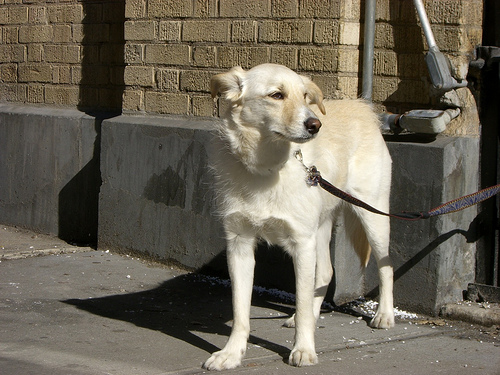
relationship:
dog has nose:
[197, 57, 407, 371] [305, 115, 324, 135]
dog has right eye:
[197, 57, 407, 371] [267, 86, 287, 105]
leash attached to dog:
[294, 143, 499, 219] [197, 57, 407, 371]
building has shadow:
[4, 6, 500, 321] [52, 3, 125, 254]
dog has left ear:
[197, 57, 407, 371] [302, 71, 325, 113]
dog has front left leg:
[197, 57, 407, 371] [285, 222, 329, 367]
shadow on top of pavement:
[68, 238, 359, 358] [13, 222, 500, 371]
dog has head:
[197, 57, 407, 371] [213, 52, 332, 151]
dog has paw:
[197, 57, 407, 371] [201, 334, 260, 374]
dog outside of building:
[197, 57, 407, 371] [4, 6, 500, 321]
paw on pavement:
[201, 334, 260, 374] [13, 222, 500, 371]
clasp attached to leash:
[294, 144, 319, 190] [294, 143, 499, 219]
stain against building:
[144, 144, 231, 223] [4, 6, 500, 321]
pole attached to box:
[356, 2, 383, 107] [394, 102, 452, 134]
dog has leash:
[197, 57, 407, 371] [294, 143, 499, 219]